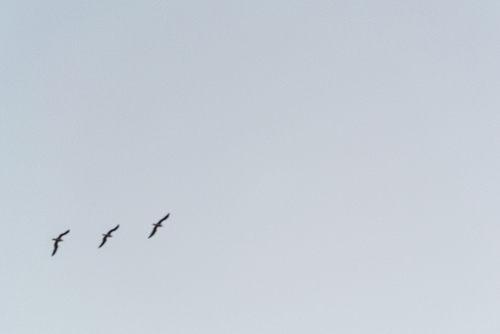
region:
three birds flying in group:
[42, 202, 178, 287]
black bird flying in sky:
[146, 208, 187, 255]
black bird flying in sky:
[97, 225, 122, 255]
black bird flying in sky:
[51, 229, 72, 259]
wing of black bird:
[154, 210, 174, 218]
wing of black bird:
[144, 224, 161, 241]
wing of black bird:
[94, 237, 109, 249]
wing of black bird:
[106, 219, 123, 233]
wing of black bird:
[47, 242, 64, 254]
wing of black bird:
[55, 225, 77, 237]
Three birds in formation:
[19, 195, 196, 255]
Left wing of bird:
[162, 207, 172, 221]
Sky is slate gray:
[2, 4, 499, 197]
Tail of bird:
[48, 237, 56, 241]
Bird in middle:
[87, 220, 119, 243]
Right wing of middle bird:
[93, 236, 108, 250]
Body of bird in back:
[50, 237, 63, 239]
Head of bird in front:
[157, 221, 166, 226]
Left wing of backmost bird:
[54, 230, 76, 236]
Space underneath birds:
[48, 262, 276, 329]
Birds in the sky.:
[7, 206, 193, 270]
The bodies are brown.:
[41, 221, 171, 250]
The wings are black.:
[131, 196, 183, 260]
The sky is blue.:
[295, 196, 486, 312]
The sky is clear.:
[185, 115, 404, 257]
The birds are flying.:
[27, 193, 192, 273]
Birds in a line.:
[40, 205, 210, 273]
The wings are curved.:
[38, 210, 75, 260]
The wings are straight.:
[139, 187, 180, 249]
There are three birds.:
[26, 204, 196, 261]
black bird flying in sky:
[48, 222, 82, 269]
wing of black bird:
[106, 219, 119, 228]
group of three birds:
[20, 195, 200, 260]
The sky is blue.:
[183, 37, 342, 150]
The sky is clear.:
[231, 176, 383, 296]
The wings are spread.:
[135, 206, 194, 249]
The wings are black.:
[139, 206, 178, 246]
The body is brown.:
[147, 215, 172, 234]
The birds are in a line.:
[40, 209, 191, 264]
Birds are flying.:
[25, 197, 175, 261]